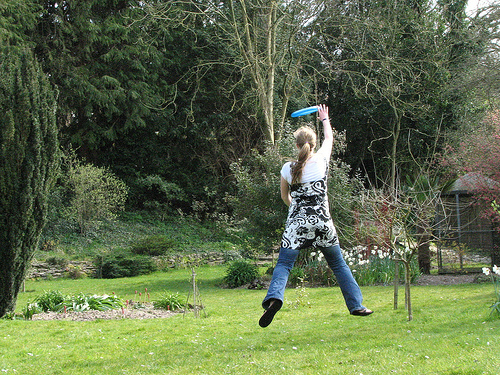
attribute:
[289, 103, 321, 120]
frisbee — blue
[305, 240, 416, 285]
flowers — white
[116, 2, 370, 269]
tree — bare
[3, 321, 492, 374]
grass — green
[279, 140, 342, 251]
shirt — artistic, white, black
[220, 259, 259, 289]
bush — green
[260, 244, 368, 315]
jeans — denim, blue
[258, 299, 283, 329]
sole — brown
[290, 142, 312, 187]
ponytail — long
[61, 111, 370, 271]
trees — small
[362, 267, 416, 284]
leaves — greeen